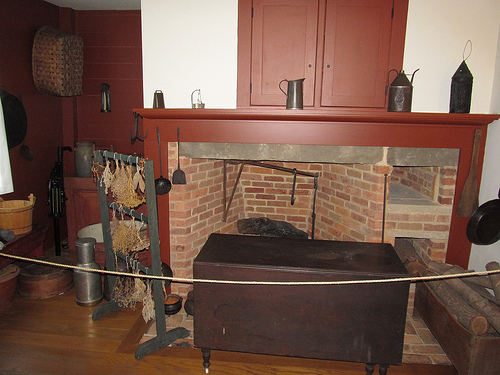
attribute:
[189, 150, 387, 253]
wall — brick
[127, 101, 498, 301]
mantle — brown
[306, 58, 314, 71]
dot — small, black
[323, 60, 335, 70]
dot — small, black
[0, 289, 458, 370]
floor — light brown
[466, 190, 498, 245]
pan — black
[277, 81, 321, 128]
container — metal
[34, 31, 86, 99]
basket — wicker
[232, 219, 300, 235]
log — blackened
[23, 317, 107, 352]
floors — hardwood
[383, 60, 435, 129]
jar — metal, oil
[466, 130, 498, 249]
paddle — wooden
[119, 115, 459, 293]
fireplace — wooden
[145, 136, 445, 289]
fireplace — brick built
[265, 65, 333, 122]
jug — pewter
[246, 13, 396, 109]
doors — brown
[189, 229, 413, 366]
box — storage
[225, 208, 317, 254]
log — inside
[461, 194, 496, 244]
frying pan — hanging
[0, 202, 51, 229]
pail — wooden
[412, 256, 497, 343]
firewood — piled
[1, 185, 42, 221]
basket — light brown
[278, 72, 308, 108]
pitcher — metal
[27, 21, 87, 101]
basket — woven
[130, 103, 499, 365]
fireplace — brick